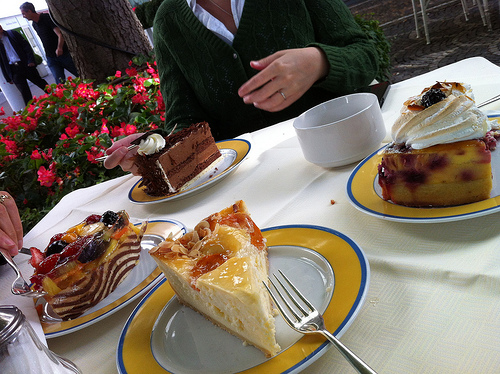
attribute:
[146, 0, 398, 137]
person — eating cake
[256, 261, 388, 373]
fork — silver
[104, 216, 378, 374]
plate — yellow, blue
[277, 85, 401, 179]
coffee cup — white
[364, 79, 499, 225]
fruit cake — off white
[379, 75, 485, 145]
topping — whipped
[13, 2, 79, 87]
man — talking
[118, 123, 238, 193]
pie — small, caramel, caram, delicious, dark brown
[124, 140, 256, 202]
plate — yellow